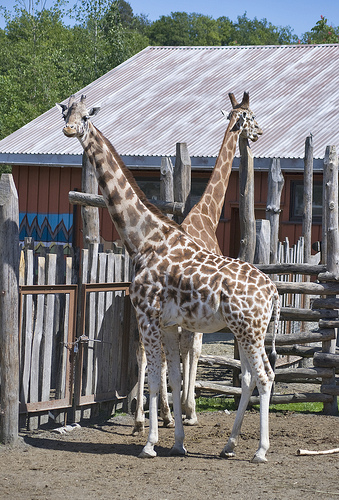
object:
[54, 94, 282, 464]
giraffe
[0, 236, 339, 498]
enclosure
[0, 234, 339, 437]
fence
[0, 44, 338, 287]
building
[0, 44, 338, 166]
metal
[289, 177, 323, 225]
window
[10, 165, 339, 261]
wall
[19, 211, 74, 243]
painting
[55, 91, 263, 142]
opposite directions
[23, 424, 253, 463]
shadow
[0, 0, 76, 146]
trees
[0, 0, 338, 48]
sky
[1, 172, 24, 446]
logs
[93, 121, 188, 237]
mane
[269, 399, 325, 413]
food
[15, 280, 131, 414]
gate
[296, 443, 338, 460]
stick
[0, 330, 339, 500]
ground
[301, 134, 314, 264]
wood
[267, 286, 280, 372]
tail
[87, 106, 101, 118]
ears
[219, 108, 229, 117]
ears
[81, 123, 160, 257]
neck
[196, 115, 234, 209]
mane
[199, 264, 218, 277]
spots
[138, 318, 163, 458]
legs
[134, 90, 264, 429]
giraffe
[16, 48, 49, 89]
leaves